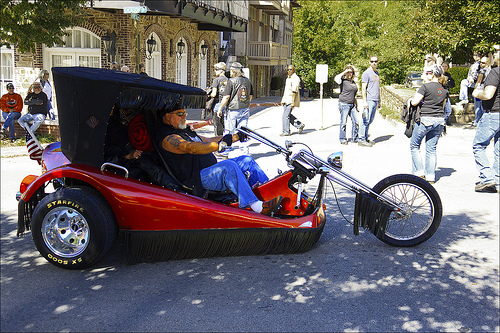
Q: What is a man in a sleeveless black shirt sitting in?
A: A red three wheeled motorcycle.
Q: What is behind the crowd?
A: Green trees.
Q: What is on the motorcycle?
A: Black roof.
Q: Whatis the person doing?
A: Driving the vehicle.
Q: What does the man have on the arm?
A: Tattoos.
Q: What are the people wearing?
A: Jeans.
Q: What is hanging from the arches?
A: Black lanterns.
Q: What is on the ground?
A: Shade from the tree.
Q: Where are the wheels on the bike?
A: One in front and two in the back.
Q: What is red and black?
A: The vehicle.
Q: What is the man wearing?
A: Black shirt.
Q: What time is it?
A: Afternoon.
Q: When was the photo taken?
A: During the daytime.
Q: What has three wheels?
A: The bike.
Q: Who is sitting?
A: The man.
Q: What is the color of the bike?
A: Red and black.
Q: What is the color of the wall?
A: Brown.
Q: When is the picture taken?
A: Daytime.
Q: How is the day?
A: Sunny.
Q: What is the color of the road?
A: Grey.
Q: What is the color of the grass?
A: Green.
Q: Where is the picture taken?
A: On the street.